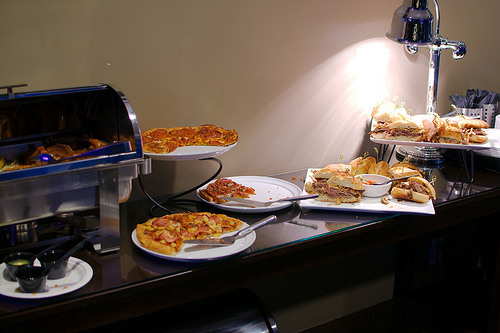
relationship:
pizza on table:
[140, 120, 234, 151] [122, 166, 476, 253]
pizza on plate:
[136, 210, 243, 255] [132, 213, 256, 260]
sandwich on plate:
[307, 111, 497, 206] [292, 164, 439, 217]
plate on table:
[194, 172, 303, 213] [277, 214, 375, 252]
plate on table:
[132, 209, 255, 260] [277, 214, 375, 252]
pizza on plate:
[136, 210, 243, 255] [131, 220, 257, 260]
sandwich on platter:
[307, 170, 365, 206] [314, 153, 437, 202]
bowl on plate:
[15, 265, 47, 291] [9, 260, 96, 301]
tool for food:
[0, 74, 155, 263] [138, 213, 243, 249]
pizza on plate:
[140, 120, 234, 151] [194, 172, 303, 213]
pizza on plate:
[196, 175, 255, 206] [132, 209, 255, 260]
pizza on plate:
[136, 210, 243, 255] [146, 143, 239, 161]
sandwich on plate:
[307, 111, 497, 206] [301, 164, 439, 215]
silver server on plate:
[186, 213, 278, 248] [132, 209, 255, 260]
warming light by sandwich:
[387, 5, 456, 65] [307, 111, 497, 206]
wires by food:
[137, 159, 226, 221] [135, 215, 245, 255]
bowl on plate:
[15, 265, 47, 291] [0, 257, 93, 298]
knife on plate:
[179, 215, 278, 250] [131, 201, 258, 258]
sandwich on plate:
[307, 111, 497, 206] [366, 127, 494, 153]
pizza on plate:
[136, 210, 243, 255] [194, 172, 303, 213]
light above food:
[397, 1, 467, 173] [138, 209, 241, 254]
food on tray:
[0, 132, 112, 174] [0, 81, 152, 253]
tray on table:
[0, 81, 152, 253] [0, 167, 498, 331]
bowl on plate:
[46, 247, 71, 279] [0, 251, 98, 301]